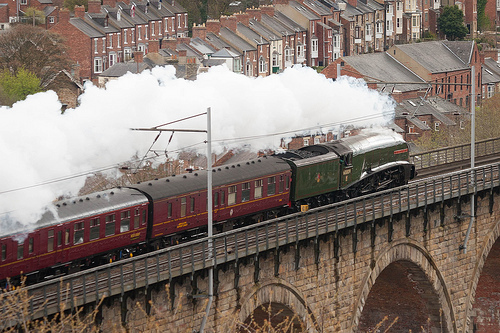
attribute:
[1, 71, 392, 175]
smoke — large, white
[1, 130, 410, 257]
train — red, green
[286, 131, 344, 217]
car — green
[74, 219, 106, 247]
windows — tall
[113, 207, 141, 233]
windows — tall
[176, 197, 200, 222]
windows — tall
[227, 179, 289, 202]
windows — tall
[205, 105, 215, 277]
pole — tall, silver, long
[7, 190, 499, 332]
bridge — brown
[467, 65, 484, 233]
pole — tall, silver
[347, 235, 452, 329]
arch — large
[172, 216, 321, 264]
train tracks — black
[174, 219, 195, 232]
words — yellow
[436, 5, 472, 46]
tree — green, large, healthy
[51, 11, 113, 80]
building — red, large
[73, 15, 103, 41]
roof — gray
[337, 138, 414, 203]
engine — green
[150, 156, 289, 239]
car — dark red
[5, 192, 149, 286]
car — dark red